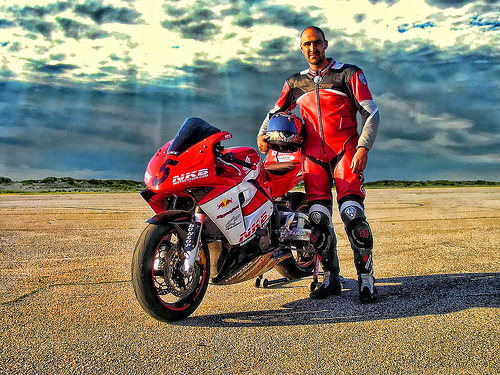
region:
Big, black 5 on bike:
[138, 155, 180, 187]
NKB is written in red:
[237, 207, 275, 241]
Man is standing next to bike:
[253, 25, 379, 302]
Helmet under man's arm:
[261, 77, 311, 159]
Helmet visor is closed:
[262, 115, 302, 137]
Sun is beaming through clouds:
[6, 4, 498, 48]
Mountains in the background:
[3, 171, 123, 198]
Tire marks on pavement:
[376, 187, 427, 222]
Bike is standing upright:
[110, 127, 314, 305]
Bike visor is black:
[164, 114, 221, 154]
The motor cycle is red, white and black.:
[131, 106, 322, 351]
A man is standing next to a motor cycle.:
[105, 17, 406, 325]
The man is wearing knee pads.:
[297, 195, 368, 225]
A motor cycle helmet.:
[250, 107, 315, 155]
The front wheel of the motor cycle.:
[120, 210, 220, 320]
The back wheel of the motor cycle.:
[275, 192, 320, 283]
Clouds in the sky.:
[10, 15, 260, 105]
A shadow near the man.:
[336, 270, 496, 337]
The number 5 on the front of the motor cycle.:
[145, 155, 186, 191]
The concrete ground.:
[17, 216, 124, 372]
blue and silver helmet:
[261, 111, 305, 154]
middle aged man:
[263, 18, 398, 315]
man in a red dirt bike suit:
[256, 26, 398, 307]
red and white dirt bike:
[108, 112, 337, 330]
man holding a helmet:
[249, 26, 389, 309]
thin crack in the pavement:
[1, 273, 136, 308]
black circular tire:
[121, 213, 217, 331]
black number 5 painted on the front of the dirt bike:
[140, 151, 184, 197]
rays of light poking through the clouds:
[6, 3, 496, 150]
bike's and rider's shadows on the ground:
[187, 278, 496, 323]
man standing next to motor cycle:
[125, 12, 420, 329]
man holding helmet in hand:
[257, 17, 407, 308]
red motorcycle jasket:
[278, 70, 385, 165]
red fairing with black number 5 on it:
[140, 97, 226, 205]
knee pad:
[307, 205, 339, 246]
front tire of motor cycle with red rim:
[131, 215, 220, 322]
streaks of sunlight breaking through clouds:
[32, 35, 237, 112]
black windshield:
[167, 107, 219, 159]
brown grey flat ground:
[400, 195, 477, 332]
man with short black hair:
[295, 21, 333, 74]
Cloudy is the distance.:
[0, 0, 138, 179]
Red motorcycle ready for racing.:
[121, 108, 331, 329]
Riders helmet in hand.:
[238, 99, 323, 167]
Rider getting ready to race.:
[254, 17, 398, 324]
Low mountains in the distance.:
[1, 167, 138, 197]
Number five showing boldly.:
[116, 102, 232, 203]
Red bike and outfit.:
[122, 13, 397, 332]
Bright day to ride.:
[2, 1, 496, 369]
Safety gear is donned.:
[242, 14, 409, 323]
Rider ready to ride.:
[242, 15, 423, 308]